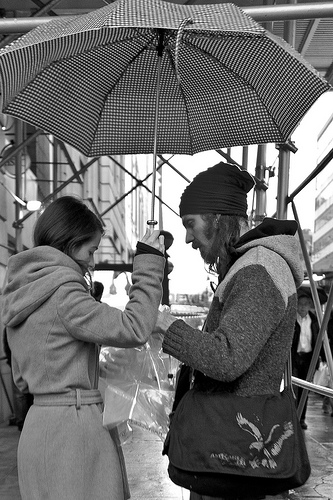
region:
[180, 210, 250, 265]
face of a man with shaggy hair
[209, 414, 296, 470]
image of an eagle on the jacket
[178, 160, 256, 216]
sock hat on a shaggy man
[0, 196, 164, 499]
nicely groomed woman with a bohemian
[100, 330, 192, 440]
a plastic bag as the center of focus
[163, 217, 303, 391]
a three toned hoodie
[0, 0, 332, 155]
a hounds tooth umbrella that is open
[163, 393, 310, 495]
shoulder bag on the shaggy man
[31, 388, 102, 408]
belt of the woman's coat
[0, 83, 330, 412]
scaffolding above the people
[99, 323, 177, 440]
shiny transparent plastic bag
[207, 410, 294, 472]
screen printed american eagle graphic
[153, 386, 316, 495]
black cloth shoulder bag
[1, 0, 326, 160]
black and white plaid umbrella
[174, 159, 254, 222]
wrinkled saggy beanie hat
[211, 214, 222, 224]
shiny silver metal earring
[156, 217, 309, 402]
heavy knit hooded sweater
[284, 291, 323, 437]
older man wearing glasses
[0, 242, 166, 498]
long soft women's jacket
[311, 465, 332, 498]
crack in the wet black tarmac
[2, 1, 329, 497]
a couple under an umbrella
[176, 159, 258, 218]
a hat on a man's head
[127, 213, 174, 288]
a woman's hand holding an umbrella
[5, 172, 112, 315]
a woman's head from the side looking downward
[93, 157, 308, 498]
man with a hat holding a piece of plastic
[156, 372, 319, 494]
the satchel of a man with a bird pattern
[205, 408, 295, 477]
bird insignia on a man's satchel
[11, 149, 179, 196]
distant view of building behind construction pylon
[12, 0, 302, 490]
a man and woman in the rain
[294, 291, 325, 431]
distant face of a pedestrian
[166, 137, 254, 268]
head of a person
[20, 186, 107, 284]
hair of a woman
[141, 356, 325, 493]
a dark messenger bag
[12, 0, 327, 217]
person holding an umbrella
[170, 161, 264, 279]
person wearing a hat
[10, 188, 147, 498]
woman wearing a coat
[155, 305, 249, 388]
arm of a person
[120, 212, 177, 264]
a hand holding a handle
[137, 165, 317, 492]
person wearing a hoodie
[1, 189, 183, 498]
woman holding a handle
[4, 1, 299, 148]
black and white umbrella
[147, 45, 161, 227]
silver handle to umbrella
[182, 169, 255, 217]
black striped beanie on head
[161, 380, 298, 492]
carrying case held by man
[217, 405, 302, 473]
image of eagle on case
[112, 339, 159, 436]
plastic bag in hand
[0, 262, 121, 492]
large coat on woman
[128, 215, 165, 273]
hand holding umbrella handle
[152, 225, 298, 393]
fleece jacket on man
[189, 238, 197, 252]
thick mustache on face